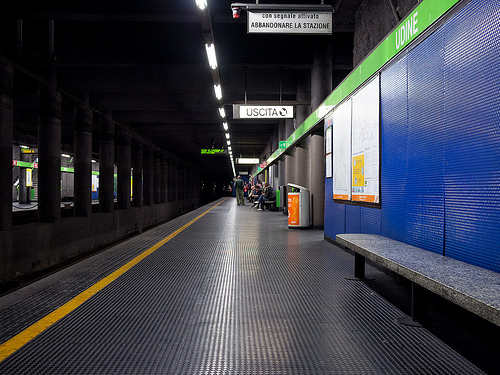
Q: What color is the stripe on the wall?
A: Green.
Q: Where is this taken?
A: Subway station.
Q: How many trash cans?
A: One.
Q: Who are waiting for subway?
A: Passengers.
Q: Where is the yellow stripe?
A: Floor.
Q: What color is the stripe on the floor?
A: Yellow.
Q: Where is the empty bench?
A: Lower right quadrant.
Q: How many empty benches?
A: One.